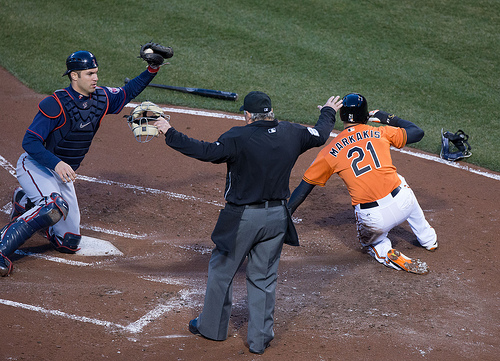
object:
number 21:
[347, 141, 382, 178]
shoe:
[387, 234, 438, 276]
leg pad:
[1, 193, 70, 277]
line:
[396, 139, 499, 185]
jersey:
[303, 122, 408, 206]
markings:
[31, 250, 188, 340]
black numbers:
[347, 142, 381, 178]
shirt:
[302, 122, 408, 205]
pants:
[354, 172, 437, 270]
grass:
[4, 0, 500, 170]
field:
[0, 0, 499, 361]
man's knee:
[357, 234, 392, 251]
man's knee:
[31, 192, 69, 224]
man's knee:
[42, 232, 82, 254]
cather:
[0, 44, 173, 277]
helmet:
[61, 50, 99, 77]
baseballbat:
[126, 79, 240, 102]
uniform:
[23, 71, 163, 173]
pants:
[0, 152, 80, 253]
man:
[153, 90, 342, 355]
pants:
[198, 199, 289, 351]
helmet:
[339, 92, 370, 124]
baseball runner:
[287, 93, 440, 276]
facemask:
[122, 99, 172, 143]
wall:
[157, 93, 192, 114]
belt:
[353, 186, 402, 210]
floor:
[45, 268, 180, 351]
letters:
[328, 130, 380, 158]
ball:
[143, 48, 153, 54]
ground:
[2, 21, 499, 360]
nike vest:
[45, 87, 107, 174]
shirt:
[164, 105, 338, 207]